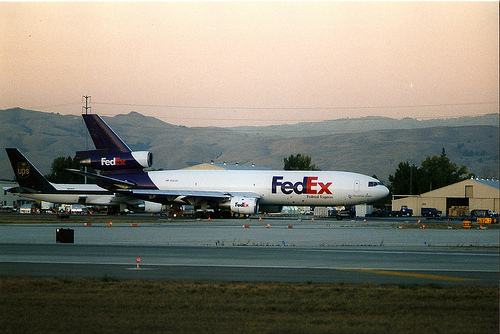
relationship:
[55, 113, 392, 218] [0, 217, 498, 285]
aircraft on runway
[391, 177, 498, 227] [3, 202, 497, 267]
building next to runway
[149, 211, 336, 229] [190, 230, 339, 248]
cones on ground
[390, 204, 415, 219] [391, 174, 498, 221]
truck in front of building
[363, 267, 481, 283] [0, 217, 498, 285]
line in runway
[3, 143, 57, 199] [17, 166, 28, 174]
wing says "ups"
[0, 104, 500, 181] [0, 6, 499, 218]
mountains in background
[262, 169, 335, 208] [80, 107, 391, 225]
name on side of aircraft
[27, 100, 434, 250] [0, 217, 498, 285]
aircraft on runway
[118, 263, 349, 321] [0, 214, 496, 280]
grass grows beside runway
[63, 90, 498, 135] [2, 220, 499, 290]
electric lines behind runway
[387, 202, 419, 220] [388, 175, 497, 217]
truck beside building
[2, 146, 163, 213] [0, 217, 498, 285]
airplane on runway